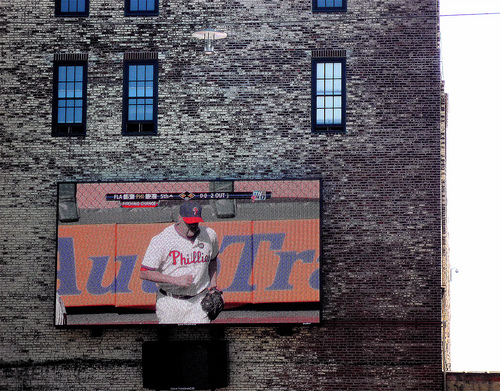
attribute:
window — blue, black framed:
[54, 54, 87, 137]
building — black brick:
[5, 3, 442, 387]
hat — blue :
[179, 199, 205, 223]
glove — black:
[205, 281, 225, 318]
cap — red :
[179, 201, 201, 224]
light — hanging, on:
[191, 20, 228, 57]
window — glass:
[117, 50, 164, 135]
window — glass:
[50, 52, 90, 135]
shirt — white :
[142, 222, 219, 297]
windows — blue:
[36, 0, 377, 136]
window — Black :
[308, 47, 350, 134]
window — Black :
[120, 52, 158, 137]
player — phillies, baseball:
[138, 201, 224, 323]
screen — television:
[48, 178, 328, 333]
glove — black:
[201, 292, 226, 316]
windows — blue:
[121, 62, 161, 126]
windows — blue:
[53, 61, 81, 125]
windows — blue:
[126, 0, 158, 12]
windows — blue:
[56, 0, 88, 15]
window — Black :
[43, 49, 96, 139]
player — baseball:
[143, 201, 237, 330]